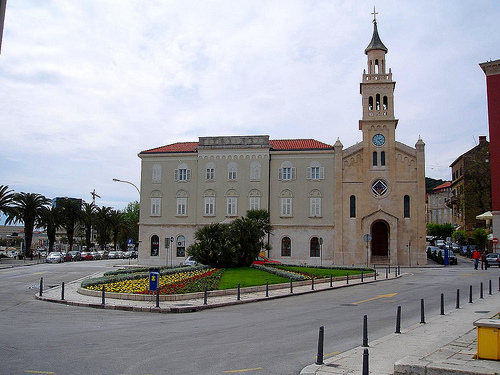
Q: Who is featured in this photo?
A: No one.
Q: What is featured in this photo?
A: A building.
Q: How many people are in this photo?
A: Two.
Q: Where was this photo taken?
A: Across the street from a building.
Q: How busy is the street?
A: It is empty.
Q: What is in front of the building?
A: A garden.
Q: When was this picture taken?
A: Daytime.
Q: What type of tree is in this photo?
A: Palm tree.